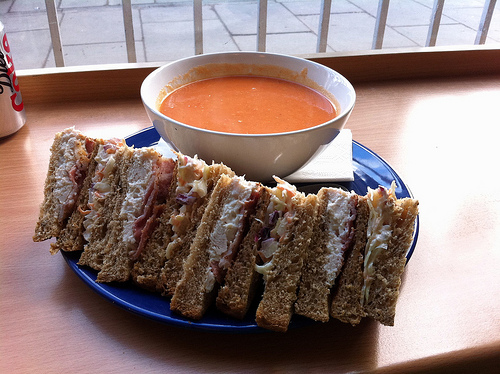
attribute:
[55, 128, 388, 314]
sandwich — large, turkey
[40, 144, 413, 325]
bread — part 